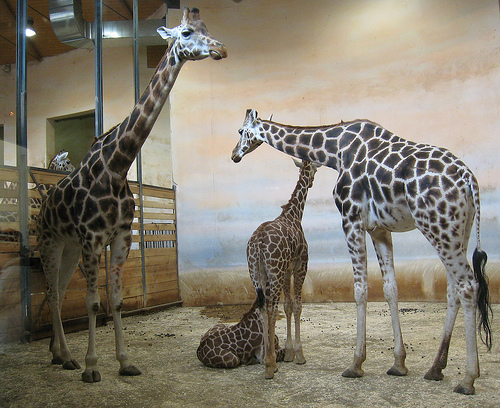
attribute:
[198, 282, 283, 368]
giraffe — small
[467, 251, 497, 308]
hair — black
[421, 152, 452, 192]
ground — in the picture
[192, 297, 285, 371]
baby giraffe — lying down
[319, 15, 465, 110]
wall — big, wooden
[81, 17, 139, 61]
light — white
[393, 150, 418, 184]
spot — brown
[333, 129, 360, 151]
spot — brown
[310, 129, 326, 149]
spot — brown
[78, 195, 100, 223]
spot — brown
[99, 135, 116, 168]
spot — brown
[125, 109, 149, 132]
spot — brown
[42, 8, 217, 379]
giraffe — fake, taller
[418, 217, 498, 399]
leg — back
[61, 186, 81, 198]
spot — brown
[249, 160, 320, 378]
giraffe — standing up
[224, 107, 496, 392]
giraffe — in the picture